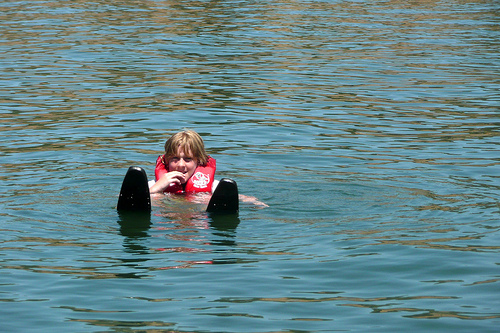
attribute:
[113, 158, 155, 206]
water ski — black, rubber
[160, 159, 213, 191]
life vest — red, white, orange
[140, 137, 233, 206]
boy — swimming, floating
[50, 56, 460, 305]
water — blue, clear, calm, large, sticking out, reflecting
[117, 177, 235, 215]
fins — black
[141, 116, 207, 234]
person — floating, young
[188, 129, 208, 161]
hair — blonde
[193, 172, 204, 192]
logo — white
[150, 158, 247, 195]
life preserver — red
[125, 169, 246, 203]
shoes — black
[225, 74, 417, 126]
waves — small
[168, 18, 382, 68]
sun — shining